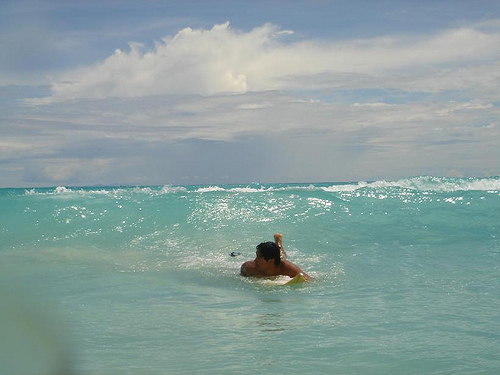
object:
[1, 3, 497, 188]
sky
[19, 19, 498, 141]
clouds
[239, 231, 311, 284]
man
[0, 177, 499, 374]
ocean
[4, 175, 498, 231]
waves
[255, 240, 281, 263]
hair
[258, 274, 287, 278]
belly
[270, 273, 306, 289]
board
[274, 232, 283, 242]
foot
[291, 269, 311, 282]
arm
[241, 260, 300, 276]
shoulder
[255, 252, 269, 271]
face